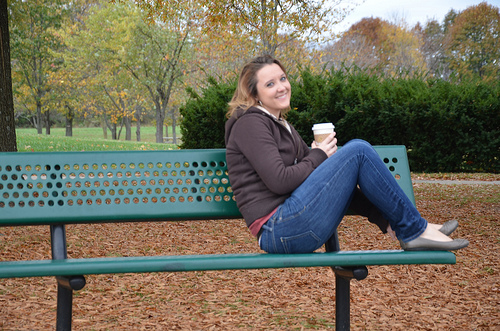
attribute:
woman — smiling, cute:
[211, 46, 478, 255]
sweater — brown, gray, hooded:
[218, 95, 330, 239]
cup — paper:
[309, 118, 338, 154]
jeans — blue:
[259, 135, 429, 255]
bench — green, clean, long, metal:
[2, 143, 461, 283]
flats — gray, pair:
[395, 219, 470, 255]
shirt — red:
[246, 208, 278, 237]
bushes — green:
[177, 64, 494, 177]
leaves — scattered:
[107, 277, 320, 329]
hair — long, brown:
[224, 60, 266, 116]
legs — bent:
[262, 133, 425, 251]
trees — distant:
[7, 2, 194, 135]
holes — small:
[84, 166, 191, 204]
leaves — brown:
[132, 143, 155, 152]